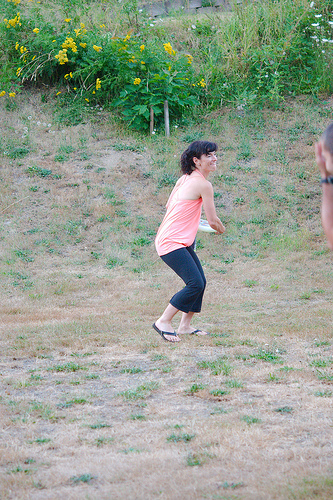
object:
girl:
[152, 140, 225, 343]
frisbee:
[198, 219, 218, 232]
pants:
[155, 246, 207, 314]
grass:
[61, 336, 105, 409]